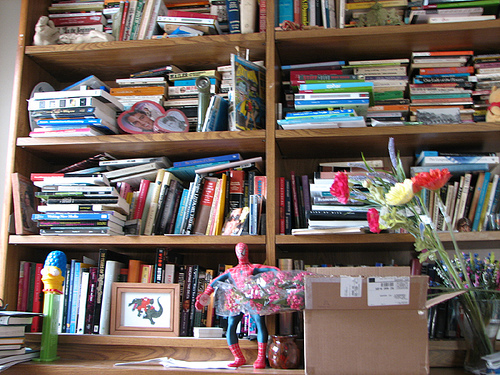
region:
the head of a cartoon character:
[40, 252, 72, 294]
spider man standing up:
[192, 237, 279, 369]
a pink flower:
[321, 171, 354, 208]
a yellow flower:
[378, 178, 420, 205]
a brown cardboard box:
[300, 260, 444, 374]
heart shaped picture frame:
[149, 110, 192, 133]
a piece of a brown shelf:
[17, 133, 274, 158]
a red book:
[277, 170, 285, 235]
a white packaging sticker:
[365, 276, 412, 304]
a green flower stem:
[432, 195, 494, 351]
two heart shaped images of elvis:
[120, 103, 185, 135]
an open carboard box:
[301, 256, 423, 372]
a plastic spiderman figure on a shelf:
[204, 250, 286, 360]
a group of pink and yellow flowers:
[332, 166, 447, 233]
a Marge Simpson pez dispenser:
[35, 243, 72, 373]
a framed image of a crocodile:
[111, 286, 175, 334]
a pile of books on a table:
[0, 303, 35, 373]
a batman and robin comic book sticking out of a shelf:
[235, 54, 265, 132]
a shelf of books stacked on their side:
[274, 46, 495, 140]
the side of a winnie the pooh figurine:
[486, 85, 498, 118]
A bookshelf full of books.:
[25, 3, 496, 314]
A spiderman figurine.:
[195, 235, 282, 372]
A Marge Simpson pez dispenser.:
[25, 246, 75, 366]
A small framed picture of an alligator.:
[105, 280, 181, 335]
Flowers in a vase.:
[330, 150, 495, 370]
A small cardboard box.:
[300, 262, 447, 368]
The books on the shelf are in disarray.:
[15, 140, 265, 235]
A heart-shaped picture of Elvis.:
[111, 95, 161, 140]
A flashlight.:
[185, 70, 211, 135]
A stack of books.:
[280, 76, 375, 137]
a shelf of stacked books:
[10, 246, 254, 334]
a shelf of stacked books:
[423, 254, 493, 342]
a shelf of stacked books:
[279, 0, 495, 25]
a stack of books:
[0, 304, 44, 366]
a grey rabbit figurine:
[25, 7, 63, 48]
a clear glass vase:
[437, 283, 497, 370]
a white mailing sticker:
[360, 273, 413, 312]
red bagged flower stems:
[205, 276, 306, 315]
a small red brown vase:
[262, 329, 301, 373]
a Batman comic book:
[229, 51, 264, 131]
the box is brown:
[268, 239, 411, 364]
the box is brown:
[380, 292, 453, 363]